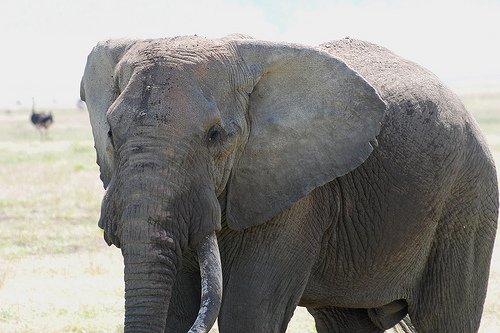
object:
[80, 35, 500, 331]
elephant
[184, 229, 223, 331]
tusk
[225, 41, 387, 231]
ear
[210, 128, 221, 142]
eye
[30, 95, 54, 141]
ostrich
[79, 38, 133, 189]
ear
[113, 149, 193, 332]
trunk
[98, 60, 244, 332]
face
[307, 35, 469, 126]
back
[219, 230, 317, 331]
front leg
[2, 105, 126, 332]
field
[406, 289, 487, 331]
leg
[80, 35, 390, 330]
head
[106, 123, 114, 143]
eye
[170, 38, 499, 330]
body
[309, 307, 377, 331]
thigh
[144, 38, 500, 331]
side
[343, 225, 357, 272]
wrinkles